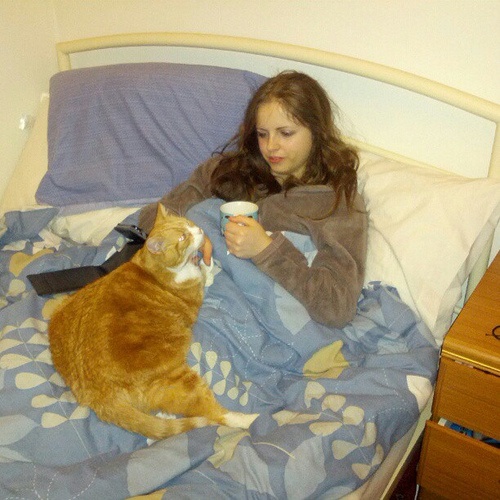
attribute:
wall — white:
[54, 2, 499, 205]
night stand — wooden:
[413, 249, 498, 496]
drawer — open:
[415, 416, 499, 499]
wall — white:
[433, 40, 483, 77]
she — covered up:
[127, 61, 367, 329]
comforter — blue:
[2, 200, 442, 497]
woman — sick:
[120, 77, 411, 334]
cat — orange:
[39, 191, 266, 433]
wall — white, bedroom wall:
[58, 14, 496, 121]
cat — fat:
[41, 208, 280, 447]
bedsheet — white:
[355, 154, 497, 329]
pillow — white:
[355, 150, 497, 345]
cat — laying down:
[37, 203, 242, 498]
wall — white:
[0, 0, 63, 197]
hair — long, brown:
[205, 65, 360, 221]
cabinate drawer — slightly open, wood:
[413, 406, 498, 495]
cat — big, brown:
[107, 214, 220, 341]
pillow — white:
[361, 144, 498, 327]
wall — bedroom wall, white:
[2, 1, 494, 42]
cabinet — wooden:
[415, 250, 497, 498]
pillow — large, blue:
[32, 58, 255, 208]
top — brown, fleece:
[132, 143, 372, 332]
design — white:
[271, 407, 320, 430]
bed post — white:
[52, 28, 496, 180]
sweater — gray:
[137, 150, 370, 328]